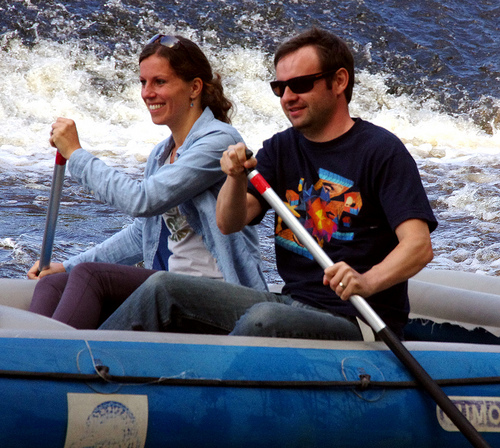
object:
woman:
[26, 32, 269, 331]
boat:
[0, 279, 499, 447]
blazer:
[63, 106, 268, 290]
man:
[97, 29, 436, 337]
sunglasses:
[261, 73, 331, 98]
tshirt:
[245, 116, 435, 328]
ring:
[337, 277, 347, 290]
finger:
[340, 282, 356, 300]